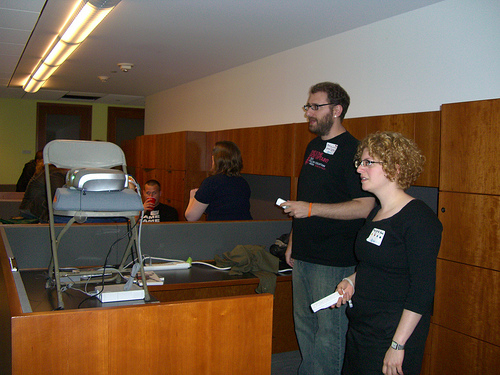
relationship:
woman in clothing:
[349, 132, 445, 374] [343, 218, 423, 374]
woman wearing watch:
[349, 132, 445, 374] [390, 338, 411, 353]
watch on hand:
[390, 338, 411, 353] [385, 341, 406, 373]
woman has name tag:
[349, 132, 445, 374] [366, 216, 398, 251]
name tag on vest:
[366, 216, 398, 251] [354, 234, 403, 292]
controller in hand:
[305, 290, 349, 319] [335, 277, 357, 310]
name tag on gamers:
[317, 140, 337, 162] [287, 81, 376, 275]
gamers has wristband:
[287, 81, 376, 275] [303, 200, 320, 225]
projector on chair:
[65, 157, 135, 200] [37, 143, 149, 264]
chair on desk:
[37, 143, 149, 264] [22, 263, 285, 338]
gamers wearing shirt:
[287, 81, 376, 275] [297, 146, 365, 263]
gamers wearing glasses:
[287, 81, 376, 275] [297, 99, 337, 112]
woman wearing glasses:
[349, 132, 445, 374] [354, 156, 391, 170]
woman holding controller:
[349, 132, 445, 374] [305, 290, 349, 319]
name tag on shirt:
[366, 216, 398, 251] [297, 146, 365, 263]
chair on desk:
[37, 143, 149, 264] [0, 273, 275, 375]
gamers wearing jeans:
[287, 81, 376, 275] [279, 259, 352, 374]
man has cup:
[134, 156, 175, 235] [144, 195, 159, 207]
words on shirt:
[302, 146, 331, 172] [297, 146, 365, 263]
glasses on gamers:
[297, 99, 337, 112] [287, 81, 376, 275]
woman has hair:
[349, 132, 445, 374] [384, 138, 420, 185]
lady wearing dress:
[349, 132, 445, 374] [343, 218, 423, 374]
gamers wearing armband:
[287, 81, 376, 275] [303, 200, 320, 225]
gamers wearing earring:
[287, 81, 376, 275] [330, 113, 339, 121]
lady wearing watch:
[349, 132, 445, 374] [390, 338, 411, 353]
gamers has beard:
[287, 81, 376, 275] [318, 114, 333, 137]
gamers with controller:
[257, 97, 434, 281] [305, 290, 349, 319]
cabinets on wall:
[134, 130, 202, 209] [183, 10, 470, 118]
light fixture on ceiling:
[31, 10, 56, 94] [119, 13, 255, 67]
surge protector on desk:
[65, 256, 195, 275] [22, 263, 285, 338]